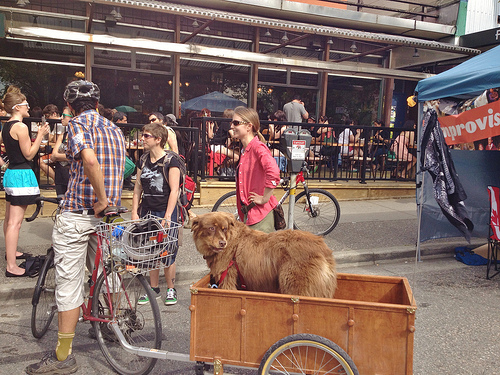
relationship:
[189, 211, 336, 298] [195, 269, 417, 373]
dog in wagon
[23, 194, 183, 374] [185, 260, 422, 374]
bicycle on wagon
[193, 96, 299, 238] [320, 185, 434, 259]
person on street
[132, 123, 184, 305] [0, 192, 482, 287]
person on sidewalk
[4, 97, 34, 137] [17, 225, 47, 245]
person on street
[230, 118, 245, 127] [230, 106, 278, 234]
sunglasses on person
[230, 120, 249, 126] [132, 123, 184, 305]
sunglasses on person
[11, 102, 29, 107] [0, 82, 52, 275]
sunglasses on person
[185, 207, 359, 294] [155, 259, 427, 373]
dog in cart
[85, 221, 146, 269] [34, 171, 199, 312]
basket on bicycle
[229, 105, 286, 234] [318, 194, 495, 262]
person standing on sidewalk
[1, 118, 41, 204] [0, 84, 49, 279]
outfit on person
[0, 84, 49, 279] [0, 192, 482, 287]
person on sidewalk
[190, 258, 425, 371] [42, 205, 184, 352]
cart connected to bike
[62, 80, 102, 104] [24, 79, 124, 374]
helmet on cyclist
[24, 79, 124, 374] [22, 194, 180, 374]
cyclist on bicycle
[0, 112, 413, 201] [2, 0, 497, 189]
metal fence in front of restaurant